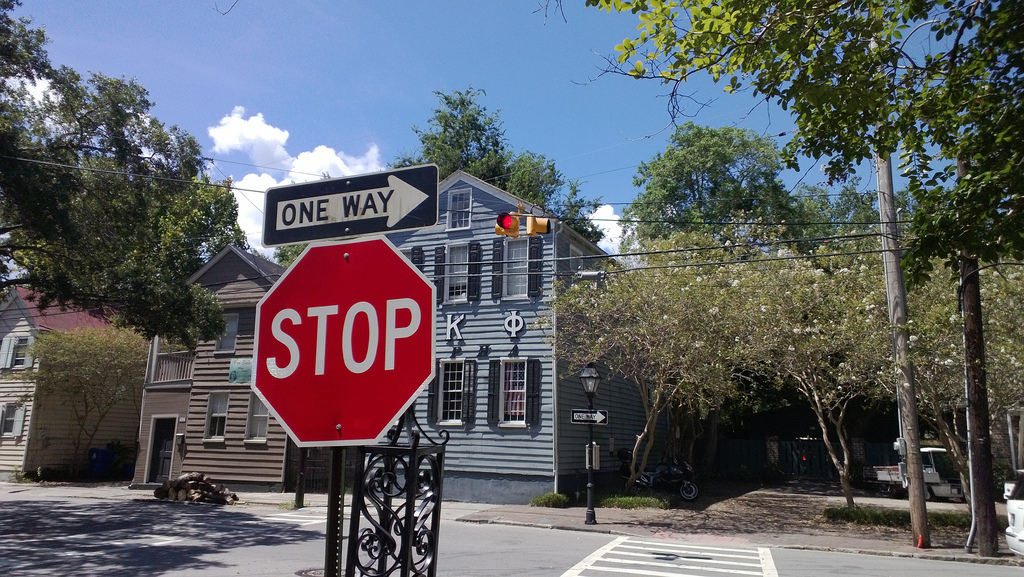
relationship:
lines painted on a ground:
[578, 522, 779, 570] [0, 482, 1024, 577]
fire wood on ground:
[168, 462, 216, 501] [7, 460, 1021, 573]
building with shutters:
[363, 170, 684, 502] [407, 244, 423, 267]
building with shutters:
[363, 170, 684, 502] [492, 238, 544, 297]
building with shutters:
[363, 170, 684, 502] [429, 357, 477, 428]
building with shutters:
[363, 170, 684, 502] [489, 357, 540, 430]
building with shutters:
[363, 170, 684, 502] [434, 243, 482, 304]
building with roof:
[1, 284, 151, 487] [7, 281, 124, 329]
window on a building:
[497, 358, 527, 429] [363, 170, 684, 502]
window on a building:
[497, 238, 532, 296] [363, 170, 684, 502]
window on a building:
[441, 235, 473, 309] [363, 170, 684, 502]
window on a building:
[440, 361, 467, 423] [363, 170, 684, 502]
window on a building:
[450, 189, 469, 227] [363, 170, 684, 502]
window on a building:
[249, 390, 268, 442] [128, 240, 351, 491]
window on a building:
[208, 390, 228, 436] [128, 240, 351, 491]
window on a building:
[219, 311, 235, 354] [128, 240, 351, 491]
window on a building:
[1, 402, 17, 431] [1, 284, 151, 487]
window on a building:
[12, 338, 23, 367] [1, 284, 151, 487]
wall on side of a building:
[26, 349, 144, 480] [1, 284, 151, 487]